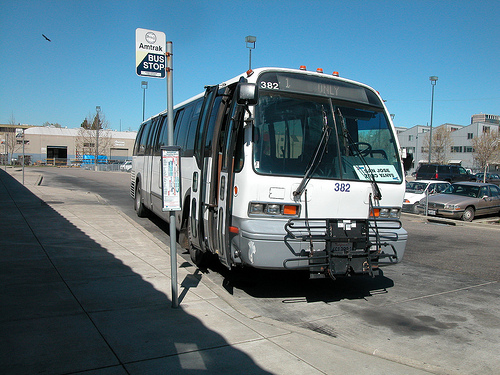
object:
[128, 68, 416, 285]
bus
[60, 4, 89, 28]
sky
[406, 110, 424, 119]
clouds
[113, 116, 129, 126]
clouds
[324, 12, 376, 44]
sky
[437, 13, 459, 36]
sky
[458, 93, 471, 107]
clouds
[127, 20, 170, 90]
sign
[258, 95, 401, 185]
windshield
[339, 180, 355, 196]
number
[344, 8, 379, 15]
sky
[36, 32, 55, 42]
bird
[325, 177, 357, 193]
number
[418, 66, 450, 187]
street lamp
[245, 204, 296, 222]
headlights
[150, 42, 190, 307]
pole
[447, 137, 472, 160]
windows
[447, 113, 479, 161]
building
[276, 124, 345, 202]
windshield wiper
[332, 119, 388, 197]
windshield wiper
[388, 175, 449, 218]
car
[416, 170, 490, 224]
car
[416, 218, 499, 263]
parking lot